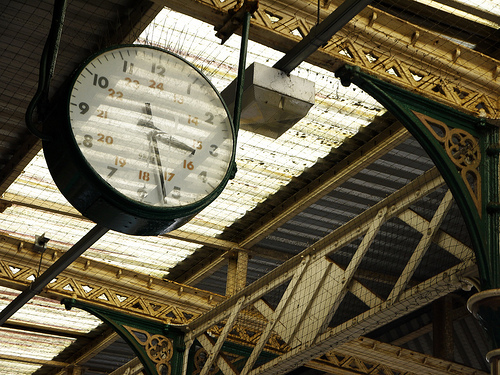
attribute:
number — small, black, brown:
[152, 55, 169, 73]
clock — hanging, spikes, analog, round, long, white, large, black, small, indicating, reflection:
[92, 64, 209, 196]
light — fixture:
[197, 34, 239, 54]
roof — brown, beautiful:
[296, 106, 400, 218]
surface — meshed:
[315, 178, 373, 232]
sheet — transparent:
[257, 98, 372, 203]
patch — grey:
[78, 5, 119, 45]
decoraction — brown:
[307, 120, 379, 164]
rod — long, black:
[372, 73, 480, 159]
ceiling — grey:
[62, 23, 117, 68]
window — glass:
[297, 114, 367, 155]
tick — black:
[153, 117, 183, 142]